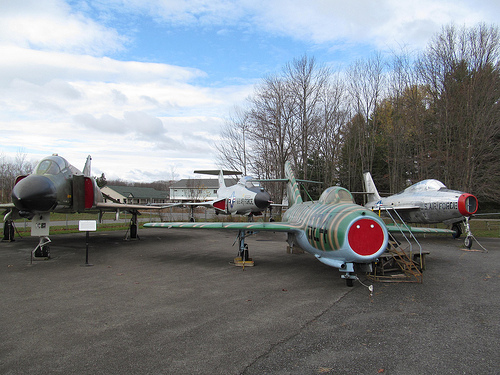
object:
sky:
[0, 22, 500, 182]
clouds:
[212, 25, 242, 38]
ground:
[0, 211, 500, 375]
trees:
[212, 104, 266, 177]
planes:
[351, 170, 500, 248]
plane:
[143, 160, 457, 288]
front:
[337, 210, 389, 262]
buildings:
[168, 178, 241, 200]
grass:
[469, 219, 500, 238]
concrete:
[22, 314, 186, 351]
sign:
[78, 219, 98, 233]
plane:
[0, 152, 165, 261]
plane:
[147, 168, 288, 222]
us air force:
[227, 190, 254, 208]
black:
[257, 195, 268, 204]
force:
[244, 198, 254, 205]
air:
[167, 122, 186, 135]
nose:
[10, 185, 38, 210]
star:
[227, 191, 237, 209]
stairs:
[404, 270, 423, 277]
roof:
[106, 184, 165, 199]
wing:
[141, 219, 304, 234]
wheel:
[345, 274, 356, 287]